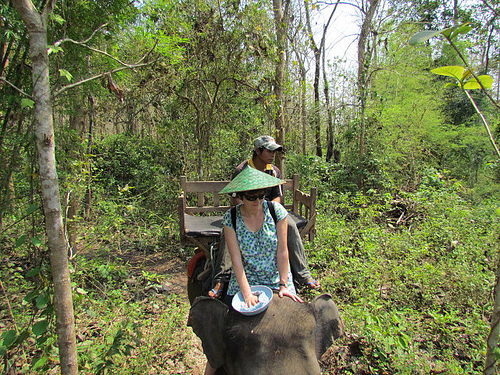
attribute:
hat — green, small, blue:
[219, 164, 284, 194]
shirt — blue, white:
[232, 204, 313, 265]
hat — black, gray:
[220, 160, 288, 200]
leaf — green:
[20, 96, 34, 115]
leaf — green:
[30, 316, 54, 335]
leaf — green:
[2, 328, 19, 349]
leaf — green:
[26, 263, 42, 278]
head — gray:
[210, 156, 295, 207]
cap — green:
[252, 134, 282, 153]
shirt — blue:
[212, 208, 291, 287]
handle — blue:
[231, 282, 274, 316]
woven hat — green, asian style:
[223, 165, 283, 192]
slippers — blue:
[289, 256, 381, 310]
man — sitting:
[225, 130, 287, 207]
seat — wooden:
[160, 165, 320, 243]